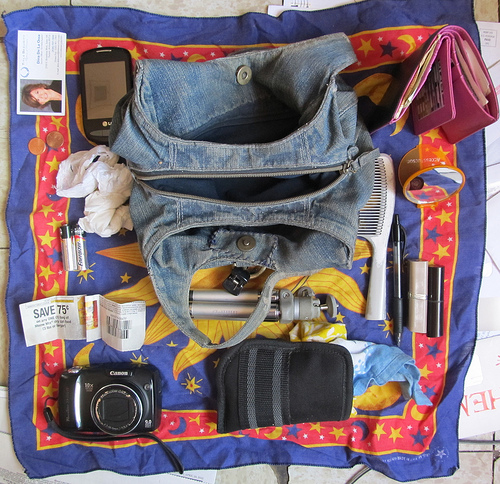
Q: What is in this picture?
A: A purse and its contents.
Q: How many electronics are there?
A: Two.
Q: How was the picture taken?
A: Directly above objects.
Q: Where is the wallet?
A: Top right corner.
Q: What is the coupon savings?
A: $0.75.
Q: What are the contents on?
A: A bandana.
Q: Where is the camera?
A: Bottom left corner.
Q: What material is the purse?
A: Jean.